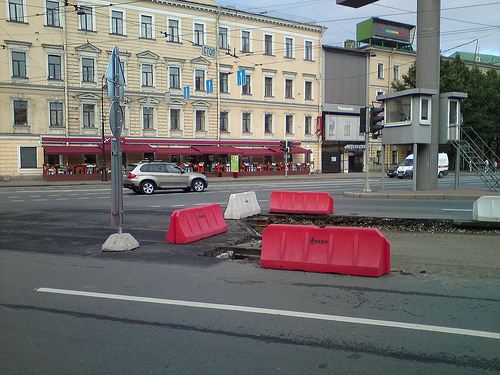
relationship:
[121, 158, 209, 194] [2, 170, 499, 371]
car on roadway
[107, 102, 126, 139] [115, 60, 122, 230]
sign on pole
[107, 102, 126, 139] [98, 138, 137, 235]
sign on pole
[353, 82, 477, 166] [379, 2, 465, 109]
boxes mounted on pole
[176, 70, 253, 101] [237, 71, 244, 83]
flags with emblem